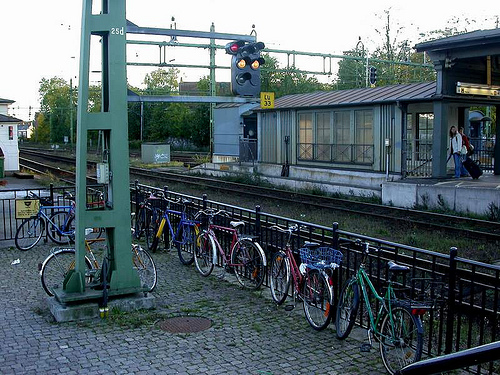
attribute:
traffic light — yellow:
[246, 40, 266, 94]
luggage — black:
[462, 153, 483, 183]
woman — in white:
[441, 123, 468, 178]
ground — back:
[448, 150, 457, 166]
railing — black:
[139, 180, 494, 340]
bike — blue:
[7, 184, 106, 249]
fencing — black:
[10, 172, 489, 334]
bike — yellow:
[28, 217, 161, 296]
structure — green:
[47, 0, 161, 321]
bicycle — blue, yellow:
[129, 202, 223, 268]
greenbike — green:
[335, 237, 424, 374]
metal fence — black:
[1, 180, 497, 374]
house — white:
[214, 53, 498, 351]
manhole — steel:
[141, 307, 226, 345]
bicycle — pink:
[255, 218, 342, 330]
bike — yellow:
[25, 215, 179, 305]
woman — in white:
[445, 125, 470, 184]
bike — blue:
[13, 187, 93, 248]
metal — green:
[57, 0, 149, 309]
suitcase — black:
[458, 152, 485, 185]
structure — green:
[57, 3, 443, 301]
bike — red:
[260, 216, 339, 327]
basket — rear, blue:
[296, 235, 346, 273]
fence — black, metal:
[6, 172, 485, 355]